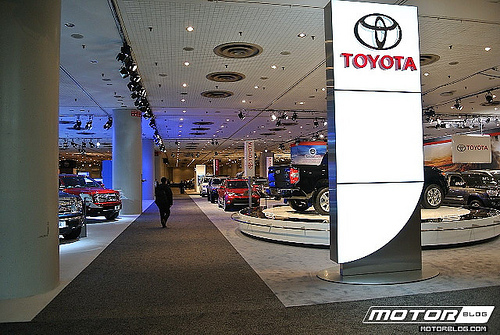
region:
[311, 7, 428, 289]
black white and red sign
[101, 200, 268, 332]
dark grey carpet on floor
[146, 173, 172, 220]
person walking on carpet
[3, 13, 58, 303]
tall light grey pillar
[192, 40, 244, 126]
grey vents on ceiling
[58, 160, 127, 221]
red truck left of man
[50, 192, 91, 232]
blue truck in front of red truck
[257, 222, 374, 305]
light grey and shiny floor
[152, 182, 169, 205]
person has black coat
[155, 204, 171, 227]
person has black pants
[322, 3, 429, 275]
the toyota sign in front of the vehicles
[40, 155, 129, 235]
the trucks next to the pillar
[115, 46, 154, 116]
the lights hanging from the roof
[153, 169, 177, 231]
the man walking down the carpet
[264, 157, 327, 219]
the bed of the truck on the platform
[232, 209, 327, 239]
the rail around the platform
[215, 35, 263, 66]
the vent on the ceiling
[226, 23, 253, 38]
the fire sprinkler placed on the ceiling of the building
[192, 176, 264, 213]
the line of cars at the car show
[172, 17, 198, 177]
the row of lights on the ceiling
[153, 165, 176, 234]
the man walking on the carpet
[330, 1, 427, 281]
the white sign in front of the display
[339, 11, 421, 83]
the toyota logo on the white sign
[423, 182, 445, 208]
the front tire of the truck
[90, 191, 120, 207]
the grill of the red truck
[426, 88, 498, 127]
the overhead light hanging on the ceiling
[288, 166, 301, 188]
the red brake light of the truck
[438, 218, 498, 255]
the rail on the round platform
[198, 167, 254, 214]
the row of cars parked in a line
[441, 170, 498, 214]
the cab of the grey truck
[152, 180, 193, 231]
the man is walkingway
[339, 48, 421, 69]
the words are written in red color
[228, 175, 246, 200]
the car is red in color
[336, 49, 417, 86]
words are written on a white board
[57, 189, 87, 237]
the car is light blue in color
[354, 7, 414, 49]
the drawing is made on a white board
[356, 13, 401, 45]
the drawing is made in black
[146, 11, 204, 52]
the roof is white in color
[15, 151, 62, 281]
the pillars are cemetrical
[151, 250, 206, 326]
the floor is rough grey in color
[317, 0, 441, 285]
A large bright sign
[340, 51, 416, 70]
Some red Toyota letters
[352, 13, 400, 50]
The symbol is black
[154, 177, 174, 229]
A man is walking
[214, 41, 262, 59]
Air vent on ceiling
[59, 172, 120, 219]
Red SUV is parked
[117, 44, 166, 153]
A row of lights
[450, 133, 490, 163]
Toyota sign hanging down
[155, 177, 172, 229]
Man is wearing suit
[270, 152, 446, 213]
Truck parked on pedestal